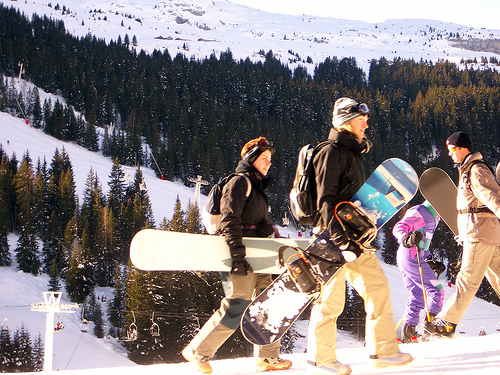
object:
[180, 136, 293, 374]
skiers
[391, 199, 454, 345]
girl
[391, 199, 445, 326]
snowsuit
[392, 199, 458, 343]
people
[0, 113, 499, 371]
snow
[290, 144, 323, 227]
backpack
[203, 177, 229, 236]
backpack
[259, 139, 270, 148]
red skigoggles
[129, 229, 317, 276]
snowboard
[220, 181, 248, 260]
arm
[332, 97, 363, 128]
hat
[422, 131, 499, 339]
man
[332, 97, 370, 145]
head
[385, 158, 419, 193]
blue stripe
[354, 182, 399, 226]
blue stripe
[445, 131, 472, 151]
hat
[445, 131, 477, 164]
man's head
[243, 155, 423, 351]
back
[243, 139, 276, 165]
headband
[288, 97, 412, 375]
man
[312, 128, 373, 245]
jacket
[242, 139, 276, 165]
hat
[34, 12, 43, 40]
tree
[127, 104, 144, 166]
tree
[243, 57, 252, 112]
tree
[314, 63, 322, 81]
tree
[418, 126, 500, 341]
train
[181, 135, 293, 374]
lady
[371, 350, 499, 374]
shadow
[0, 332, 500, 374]
ground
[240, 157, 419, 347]
snowboard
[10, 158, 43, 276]
trees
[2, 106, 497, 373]
ski slope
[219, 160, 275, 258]
ski jacket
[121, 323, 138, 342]
ski lift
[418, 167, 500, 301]
snowboard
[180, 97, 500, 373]
group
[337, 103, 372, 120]
goggles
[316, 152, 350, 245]
arm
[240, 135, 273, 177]
woman's head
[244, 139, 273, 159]
ski googles